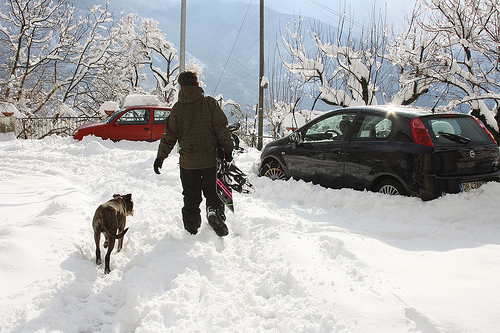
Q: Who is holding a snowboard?
A: A person.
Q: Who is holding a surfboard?
A: A man.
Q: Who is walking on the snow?
A: A man and dog.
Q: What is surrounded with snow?
A: A car.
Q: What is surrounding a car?
A: The snow.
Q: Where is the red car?
A: Surrounded in snow.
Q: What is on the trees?
A: Trees are covered in snow.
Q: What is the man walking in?
A: Man walking in the snow.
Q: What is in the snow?
A: Foot prints in the snow.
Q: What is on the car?
A: No snow.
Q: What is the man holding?
A: A man holding a snowboard.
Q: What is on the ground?
A: Snow completely covering the ground.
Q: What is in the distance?
A: An outline of mountains.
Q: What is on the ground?
A: Snow.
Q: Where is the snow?
A: On the ground.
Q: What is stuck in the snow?
A: A black car.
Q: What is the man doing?
A: Walking in the snow.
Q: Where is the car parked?
A: In the snow.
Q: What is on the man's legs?
A: Black pants.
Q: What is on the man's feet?
A: Black boots.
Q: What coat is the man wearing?
A: A brown coat.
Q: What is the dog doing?
A: Walking.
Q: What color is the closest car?
A: Black.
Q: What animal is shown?
A: Dog.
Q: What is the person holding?
A: Snowboard.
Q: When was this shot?
A: Daytime.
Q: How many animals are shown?
A: 1.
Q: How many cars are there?
A: 2.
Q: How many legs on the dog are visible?
A: 4.